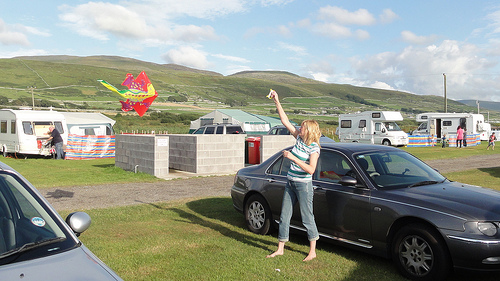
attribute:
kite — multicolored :
[95, 69, 159, 120]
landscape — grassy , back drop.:
[57, 195, 497, 279]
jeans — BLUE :
[276, 177, 319, 243]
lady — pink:
[264, 94, 375, 262]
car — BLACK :
[226, 139, 498, 276]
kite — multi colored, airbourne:
[99, 73, 156, 118]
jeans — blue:
[278, 180, 323, 243]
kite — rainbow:
[78, 59, 167, 159]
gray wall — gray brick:
[113, 127, 173, 187]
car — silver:
[3, 148, 130, 275]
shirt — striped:
[284, 132, 321, 183]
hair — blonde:
[299, 119, 323, 149]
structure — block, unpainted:
[116, 117, 299, 178]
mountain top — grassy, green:
[1, 47, 226, 79]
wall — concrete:
[108, 130, 178, 183]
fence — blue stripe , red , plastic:
[60, 129, 117, 160]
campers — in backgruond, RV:
[337, 109, 492, 144]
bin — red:
[246, 131, 265, 165]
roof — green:
[226, 105, 296, 129]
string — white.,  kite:
[207, 38, 270, 86]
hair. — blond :
[307, 124, 317, 138]